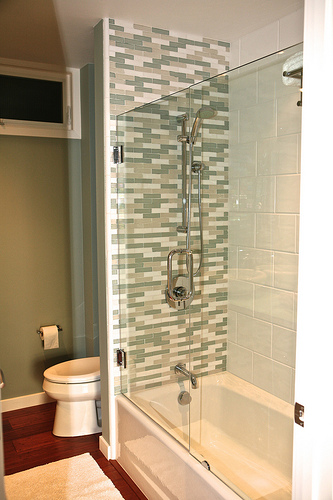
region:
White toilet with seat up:
[31, 353, 107, 443]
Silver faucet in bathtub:
[168, 359, 203, 392]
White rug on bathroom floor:
[4, 449, 128, 498]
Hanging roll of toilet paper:
[39, 320, 61, 352]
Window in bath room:
[0, 72, 68, 127]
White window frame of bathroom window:
[0, 54, 85, 145]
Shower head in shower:
[169, 103, 220, 161]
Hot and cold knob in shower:
[166, 282, 197, 305]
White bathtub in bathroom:
[113, 368, 294, 499]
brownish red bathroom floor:
[0, 399, 155, 499]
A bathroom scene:
[4, 7, 326, 491]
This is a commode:
[42, 352, 102, 437]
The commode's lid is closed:
[42, 354, 101, 385]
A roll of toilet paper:
[36, 322, 65, 351]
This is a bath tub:
[114, 371, 294, 499]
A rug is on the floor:
[1, 451, 130, 499]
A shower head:
[196, 101, 218, 120]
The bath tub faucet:
[173, 360, 202, 389]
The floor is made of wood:
[2, 402, 148, 499]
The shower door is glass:
[112, 72, 293, 498]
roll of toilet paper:
[34, 315, 65, 350]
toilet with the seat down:
[39, 362, 107, 447]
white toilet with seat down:
[40, 352, 101, 431]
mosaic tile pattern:
[119, 26, 209, 72]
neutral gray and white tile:
[115, 19, 194, 65]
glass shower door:
[119, 115, 218, 421]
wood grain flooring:
[11, 409, 48, 459]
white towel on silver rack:
[274, 47, 302, 100]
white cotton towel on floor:
[15, 458, 110, 496]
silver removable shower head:
[179, 103, 215, 305]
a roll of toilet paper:
[37, 323, 62, 351]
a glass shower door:
[108, 20, 305, 498]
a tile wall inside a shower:
[108, 19, 227, 393]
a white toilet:
[43, 353, 101, 439]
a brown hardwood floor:
[0, 401, 147, 499]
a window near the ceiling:
[0, 60, 83, 136]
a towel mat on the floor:
[5, 450, 125, 499]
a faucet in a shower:
[172, 359, 202, 390]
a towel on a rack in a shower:
[276, 48, 300, 81]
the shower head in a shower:
[180, 101, 217, 142]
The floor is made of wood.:
[1, 400, 148, 498]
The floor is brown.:
[0, 401, 148, 498]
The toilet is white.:
[41, 355, 100, 437]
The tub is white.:
[115, 369, 293, 499]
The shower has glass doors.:
[116, 40, 306, 499]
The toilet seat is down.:
[41, 355, 101, 435]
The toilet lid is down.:
[41, 355, 101, 436]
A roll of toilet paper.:
[38, 322, 59, 348]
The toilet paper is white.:
[38, 322, 59, 349]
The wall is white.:
[229, 5, 306, 404]